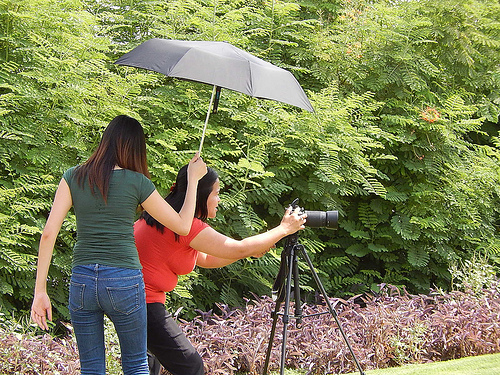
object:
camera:
[277, 200, 342, 236]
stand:
[259, 229, 364, 374]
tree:
[2, 2, 498, 328]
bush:
[2, 280, 494, 374]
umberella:
[118, 24, 323, 124]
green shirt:
[63, 169, 157, 267]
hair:
[72, 114, 150, 204]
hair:
[139, 163, 219, 242]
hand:
[27, 292, 55, 334]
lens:
[304, 210, 337, 225]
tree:
[376, 94, 496, 287]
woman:
[130, 152, 306, 373]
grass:
[392, 358, 497, 374]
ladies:
[34, 110, 208, 374]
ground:
[238, 350, 479, 373]